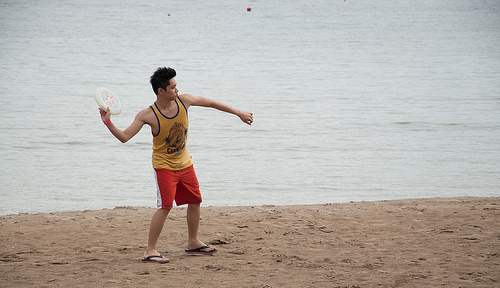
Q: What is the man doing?
A: Playing frisbee.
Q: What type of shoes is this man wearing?
A: Flip flops.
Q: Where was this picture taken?
A: The beach.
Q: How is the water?
A: Calm.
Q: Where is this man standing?
A: On the sand.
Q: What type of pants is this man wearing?
A: Shorts.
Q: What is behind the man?
A: The water.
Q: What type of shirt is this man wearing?
A: A tank top.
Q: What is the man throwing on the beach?
A: A frisbee.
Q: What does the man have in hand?
A: A frisbee.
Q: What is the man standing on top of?
A: Sand.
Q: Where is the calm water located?
A: By the beach.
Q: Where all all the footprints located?
A: On the sand.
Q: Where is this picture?
A: The beach.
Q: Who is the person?
A: A man.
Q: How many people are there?
A: One.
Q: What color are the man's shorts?
A: Red.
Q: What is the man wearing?
A: A shirt.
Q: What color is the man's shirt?
A: Yellow.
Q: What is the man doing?
A: Throwing a frisbee.